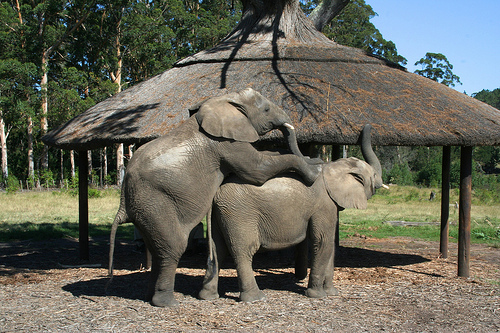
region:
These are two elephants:
[33, 94, 430, 273]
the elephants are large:
[89, 134, 364, 330]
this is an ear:
[214, 84, 302, 168]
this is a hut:
[222, 29, 388, 241]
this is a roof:
[316, 40, 370, 149]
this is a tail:
[76, 219, 154, 309]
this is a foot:
[164, 294, 304, 318]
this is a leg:
[205, 254, 321, 292]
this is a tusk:
[262, 102, 277, 117]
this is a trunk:
[265, 98, 327, 215]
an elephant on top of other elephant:
[97, 83, 394, 308]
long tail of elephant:
[102, 188, 127, 288]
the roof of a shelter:
[61, 9, 497, 149]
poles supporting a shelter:
[431, 139, 478, 279]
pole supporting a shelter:
[69, 143, 97, 254]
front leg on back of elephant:
[221, 137, 330, 191]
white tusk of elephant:
[379, 176, 392, 195]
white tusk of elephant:
[281, 113, 301, 137]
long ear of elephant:
[193, 96, 265, 149]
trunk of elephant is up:
[356, 112, 388, 178]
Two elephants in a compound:
[107, 85, 385, 307]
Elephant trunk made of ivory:
[281, 120, 296, 131]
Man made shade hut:
[38, 8, 498, 280]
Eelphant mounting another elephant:
[106, 85, 393, 308]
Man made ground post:
[457, 141, 472, 278]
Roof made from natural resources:
[38, 0, 498, 147]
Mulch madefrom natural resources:
[0, 230, 498, 331]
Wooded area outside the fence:
[1, 0, 499, 194]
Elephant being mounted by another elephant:
[107, 85, 395, 309]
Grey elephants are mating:
[117, 88, 415, 320]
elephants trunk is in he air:
[339, 120, 394, 223]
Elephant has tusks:
[196, 80, 317, 169]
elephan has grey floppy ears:
[173, 75, 279, 159]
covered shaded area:
[70, 9, 471, 208]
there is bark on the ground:
[58, 265, 376, 331]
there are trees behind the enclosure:
[24, 8, 366, 315]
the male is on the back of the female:
[114, 94, 269, 257]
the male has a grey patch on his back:
[132, 126, 209, 184]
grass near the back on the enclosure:
[363, 175, 491, 263]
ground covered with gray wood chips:
[10, 233, 495, 329]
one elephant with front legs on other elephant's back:
[210, 86, 382, 296]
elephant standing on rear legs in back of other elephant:
[120, 90, 280, 300]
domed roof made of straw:
[67, 10, 492, 151]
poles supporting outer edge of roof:
[66, 150, 481, 276]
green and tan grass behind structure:
[5, 171, 490, 241]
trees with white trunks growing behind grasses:
[5, 5, 490, 180]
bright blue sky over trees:
[351, 0, 493, 100]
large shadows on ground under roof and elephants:
[0, 215, 425, 305]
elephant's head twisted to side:
[325, 122, 390, 213]